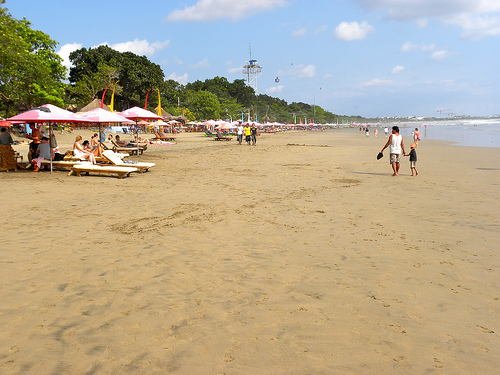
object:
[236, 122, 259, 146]
people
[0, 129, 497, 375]
beach